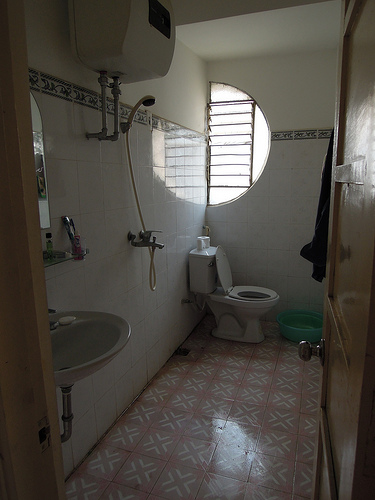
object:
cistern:
[182, 244, 220, 297]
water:
[126, 88, 168, 286]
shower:
[76, 5, 227, 404]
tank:
[192, 240, 274, 336]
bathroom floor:
[78, 345, 317, 498]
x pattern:
[234, 380, 269, 407]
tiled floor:
[65, 315, 321, 499]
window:
[207, 81, 271, 207]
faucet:
[125, 225, 176, 253]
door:
[304, 6, 370, 492]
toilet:
[191, 231, 285, 351]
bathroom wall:
[32, 19, 210, 445]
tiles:
[40, 105, 195, 338]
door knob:
[296, 332, 328, 364]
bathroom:
[28, 3, 353, 490]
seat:
[228, 278, 277, 307]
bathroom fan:
[64, 1, 178, 88]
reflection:
[143, 74, 282, 215]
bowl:
[281, 300, 317, 344]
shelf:
[39, 241, 95, 273]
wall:
[40, 27, 212, 410]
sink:
[51, 305, 131, 389]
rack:
[203, 97, 257, 189]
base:
[205, 321, 264, 349]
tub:
[280, 301, 326, 346]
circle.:
[205, 77, 272, 202]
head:
[130, 93, 166, 118]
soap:
[58, 306, 79, 321]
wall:
[113, 293, 155, 357]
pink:
[43, 453, 160, 464]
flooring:
[75, 447, 220, 500]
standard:
[147, 298, 258, 397]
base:
[219, 301, 273, 350]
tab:
[122, 324, 125, 340]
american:
[97, 483, 205, 500]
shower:
[99, 225, 182, 289]